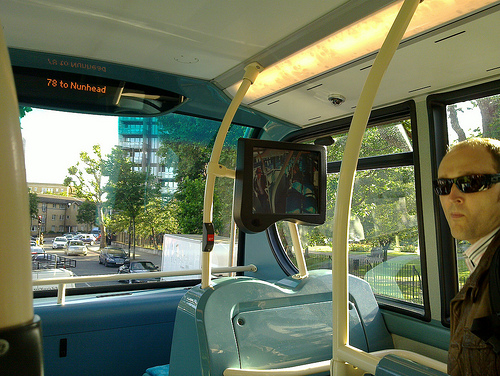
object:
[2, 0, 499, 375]
bus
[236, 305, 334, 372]
reflection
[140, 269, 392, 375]
seat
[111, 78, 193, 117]
mirror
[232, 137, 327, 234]
telivision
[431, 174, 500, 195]
glasses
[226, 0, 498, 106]
light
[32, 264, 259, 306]
rail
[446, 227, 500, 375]
jacket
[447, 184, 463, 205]
nose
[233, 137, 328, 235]
monitor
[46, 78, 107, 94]
letters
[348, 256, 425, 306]
fence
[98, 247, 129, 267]
car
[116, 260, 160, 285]
car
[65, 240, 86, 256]
car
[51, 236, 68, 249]
car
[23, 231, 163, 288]
street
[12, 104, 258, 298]
windshield.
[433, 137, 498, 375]
man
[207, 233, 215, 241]
button